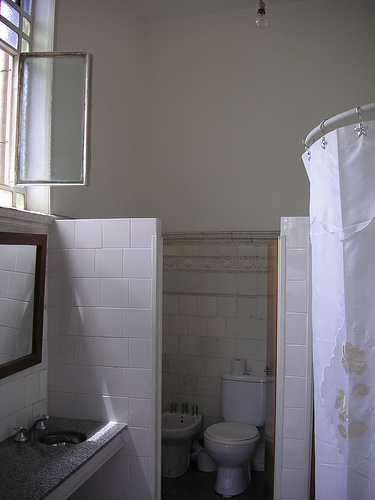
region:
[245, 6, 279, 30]
Light on the ceiling.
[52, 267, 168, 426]
The walls are tile.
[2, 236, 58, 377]
Mirror on the wall.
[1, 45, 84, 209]
The window is open.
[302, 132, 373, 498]
The shower curtain is white.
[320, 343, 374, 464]
Design on the curtain.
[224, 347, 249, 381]
Toilet paper on the toilet.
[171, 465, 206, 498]
The floor is tiled.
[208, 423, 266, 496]
The toilet is white.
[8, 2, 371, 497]
Taken in a bathroom.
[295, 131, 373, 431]
Stained shower curtain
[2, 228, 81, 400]
Mirror with brown wooden trim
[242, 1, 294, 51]
Light bulb on the ceiling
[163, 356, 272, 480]
White toilet with bidet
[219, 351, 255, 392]
Toilet paper role on toilet water tank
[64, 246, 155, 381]
White tiles on divider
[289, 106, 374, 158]
Curved shower rod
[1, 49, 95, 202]
Glass pane window with iron trim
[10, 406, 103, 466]
Sink in the bathroom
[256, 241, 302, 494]
Wooden toilet door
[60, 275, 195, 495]
the tiles is clean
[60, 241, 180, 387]
the tiles is clean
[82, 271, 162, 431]
the tiles is clean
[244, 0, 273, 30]
a light bulb hanging from a ceiling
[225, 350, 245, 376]
a roll of toilet paper on the back of a toilet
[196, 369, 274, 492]
a white toilet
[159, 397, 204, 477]
a bidet next to a toilet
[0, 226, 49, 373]
a mirror above a sink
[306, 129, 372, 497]
a white rose decorated shower curtain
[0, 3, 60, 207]
a window high in a bathroom wall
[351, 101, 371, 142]
a silver star shower hook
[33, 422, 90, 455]
a bathroom sink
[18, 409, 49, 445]
a faucet on a bathroom sink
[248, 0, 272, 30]
the light bulb in the ceiling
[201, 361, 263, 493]
the white toilet bowl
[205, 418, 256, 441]
the white toilet seat cover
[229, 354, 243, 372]
the toilet paper roll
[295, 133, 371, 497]
the white shower curtain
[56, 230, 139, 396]
the white tiles on the wall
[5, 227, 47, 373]
the bathroom mirror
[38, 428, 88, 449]
the bathroom sink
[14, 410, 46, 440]
the water faucet fixtures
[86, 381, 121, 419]
the sun shining on the wall